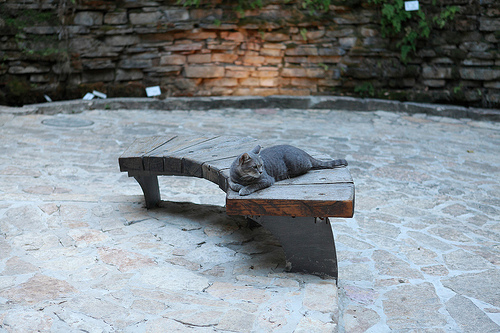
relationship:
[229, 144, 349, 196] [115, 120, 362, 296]
cat on bench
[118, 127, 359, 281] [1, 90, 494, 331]
bench on ground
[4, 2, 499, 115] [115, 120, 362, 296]
wall by bench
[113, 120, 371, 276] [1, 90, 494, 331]
platform on ground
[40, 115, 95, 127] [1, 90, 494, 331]
cover on ground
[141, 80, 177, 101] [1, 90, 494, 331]
sign on ground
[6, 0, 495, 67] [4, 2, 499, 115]
plants hanging off wall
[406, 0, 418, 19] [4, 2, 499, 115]
sign on wall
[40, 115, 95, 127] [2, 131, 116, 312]
cover on ground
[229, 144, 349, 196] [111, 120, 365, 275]
cat sitting on a bench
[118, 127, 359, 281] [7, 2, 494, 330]
bench in a courtyard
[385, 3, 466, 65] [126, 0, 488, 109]
ivy growing on a wall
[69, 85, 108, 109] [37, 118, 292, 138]
paper laying on ground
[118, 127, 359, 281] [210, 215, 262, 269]
bench casting a shadow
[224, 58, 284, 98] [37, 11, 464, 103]
light on wall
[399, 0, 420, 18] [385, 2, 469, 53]
paper on ivy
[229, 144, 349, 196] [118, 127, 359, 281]
cat on bench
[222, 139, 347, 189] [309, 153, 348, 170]
cat has stripes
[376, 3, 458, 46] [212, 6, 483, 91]
plants are on fence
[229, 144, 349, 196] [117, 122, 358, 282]
cat on table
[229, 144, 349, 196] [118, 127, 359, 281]
cat sitting on bench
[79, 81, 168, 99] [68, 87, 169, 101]
pieces of paper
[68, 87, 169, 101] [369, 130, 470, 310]
paper on ground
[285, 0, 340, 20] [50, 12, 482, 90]
vegetation growing on wall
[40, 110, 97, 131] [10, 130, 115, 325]
cover in street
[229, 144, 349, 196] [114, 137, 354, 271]
cat sitting on bench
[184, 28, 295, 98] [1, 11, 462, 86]
light shines on wall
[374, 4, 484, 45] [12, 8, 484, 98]
vegetation growing on wall